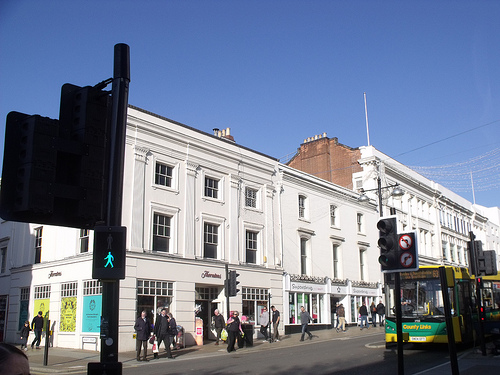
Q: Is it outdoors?
A: Yes, it is outdoors.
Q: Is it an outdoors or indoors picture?
A: It is outdoors.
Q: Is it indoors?
A: No, it is outdoors.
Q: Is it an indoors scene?
A: No, it is outdoors.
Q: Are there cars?
A: No, there are no cars.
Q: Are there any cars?
A: No, there are no cars.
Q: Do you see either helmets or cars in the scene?
A: No, there are no cars or helmets.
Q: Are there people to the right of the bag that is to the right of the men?
A: Yes, there is a person to the right of the bag.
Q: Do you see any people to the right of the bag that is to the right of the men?
A: Yes, there is a person to the right of the bag.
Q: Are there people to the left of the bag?
A: No, the person is to the right of the bag.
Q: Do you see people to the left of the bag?
A: No, the person is to the right of the bag.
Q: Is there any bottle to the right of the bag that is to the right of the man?
A: No, there is a person to the right of the bag.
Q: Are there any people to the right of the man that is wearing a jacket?
A: No, the person is to the left of the man.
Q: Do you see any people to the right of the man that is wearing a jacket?
A: No, the person is to the left of the man.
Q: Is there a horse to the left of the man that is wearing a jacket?
A: No, there is a person to the left of the man.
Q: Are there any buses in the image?
A: Yes, there is a bus.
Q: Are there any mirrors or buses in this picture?
A: Yes, there is a bus.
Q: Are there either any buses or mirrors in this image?
A: Yes, there is a bus.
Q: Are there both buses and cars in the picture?
A: No, there is a bus but no cars.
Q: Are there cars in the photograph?
A: No, there are no cars.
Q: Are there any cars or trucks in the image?
A: No, there are no cars or trucks.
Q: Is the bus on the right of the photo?
A: Yes, the bus is on the right of the image.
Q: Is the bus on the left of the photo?
A: No, the bus is on the right of the image.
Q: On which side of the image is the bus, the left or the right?
A: The bus is on the right of the image.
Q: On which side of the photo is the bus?
A: The bus is on the right of the image.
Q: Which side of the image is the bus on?
A: The bus is on the right of the image.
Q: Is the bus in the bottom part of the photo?
A: Yes, the bus is in the bottom of the image.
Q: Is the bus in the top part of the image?
A: No, the bus is in the bottom of the image.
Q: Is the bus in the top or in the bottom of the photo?
A: The bus is in the bottom of the image.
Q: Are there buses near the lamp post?
A: Yes, there is a bus near the lamp post.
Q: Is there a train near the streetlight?
A: No, there is a bus near the streetlight.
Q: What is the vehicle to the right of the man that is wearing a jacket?
A: The vehicle is a bus.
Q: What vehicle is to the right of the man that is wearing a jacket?
A: The vehicle is a bus.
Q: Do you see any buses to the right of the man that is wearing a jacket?
A: Yes, there is a bus to the right of the man.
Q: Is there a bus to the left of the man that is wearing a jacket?
A: No, the bus is to the right of the man.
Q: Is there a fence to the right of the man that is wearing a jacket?
A: No, there is a bus to the right of the man.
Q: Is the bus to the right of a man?
A: Yes, the bus is to the right of a man.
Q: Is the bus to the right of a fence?
A: No, the bus is to the right of a man.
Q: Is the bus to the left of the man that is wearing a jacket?
A: No, the bus is to the right of the man.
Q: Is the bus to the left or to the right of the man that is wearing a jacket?
A: The bus is to the right of the man.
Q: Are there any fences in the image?
A: No, there are no fences.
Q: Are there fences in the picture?
A: No, there are no fences.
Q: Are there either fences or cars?
A: No, there are no fences or cars.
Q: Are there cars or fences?
A: No, there are no fences or cars.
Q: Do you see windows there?
A: Yes, there is a window.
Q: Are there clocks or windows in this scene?
A: Yes, there is a window.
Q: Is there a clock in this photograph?
A: No, there are no clocks.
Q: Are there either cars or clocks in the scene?
A: No, there are no clocks or cars.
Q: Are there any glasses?
A: No, there are no glasses.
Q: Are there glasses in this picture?
A: No, there are no glasses.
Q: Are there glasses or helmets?
A: No, there are no glasses or helmets.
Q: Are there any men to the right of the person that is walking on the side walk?
A: Yes, there is a man to the right of the person.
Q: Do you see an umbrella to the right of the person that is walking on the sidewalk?
A: No, there is a man to the right of the person.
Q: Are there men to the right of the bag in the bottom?
A: Yes, there is a man to the right of the bag.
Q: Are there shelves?
A: No, there are no shelves.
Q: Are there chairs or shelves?
A: No, there are no shelves or chairs.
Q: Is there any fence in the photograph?
A: No, there are no fences.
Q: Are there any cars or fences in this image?
A: No, there are no fences or cars.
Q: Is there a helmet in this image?
A: No, there are no helmets.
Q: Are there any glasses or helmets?
A: No, there are no helmets or glasses.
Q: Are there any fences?
A: No, there are no fences.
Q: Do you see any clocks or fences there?
A: No, there are no fences or clocks.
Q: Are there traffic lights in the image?
A: Yes, there is a traffic light.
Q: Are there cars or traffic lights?
A: Yes, there is a traffic light.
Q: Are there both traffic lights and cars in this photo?
A: No, there is a traffic light but no cars.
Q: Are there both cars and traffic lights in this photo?
A: No, there is a traffic light but no cars.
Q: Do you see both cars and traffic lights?
A: No, there is a traffic light but no cars.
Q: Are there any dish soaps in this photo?
A: No, there are no dish soaps.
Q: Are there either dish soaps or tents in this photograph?
A: No, there are no dish soaps or tents.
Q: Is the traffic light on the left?
A: Yes, the traffic light is on the left of the image.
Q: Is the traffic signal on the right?
A: No, the traffic signal is on the left of the image.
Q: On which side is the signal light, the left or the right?
A: The signal light is on the left of the image.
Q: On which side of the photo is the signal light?
A: The signal light is on the left of the image.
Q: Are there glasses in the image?
A: No, there are no glasses.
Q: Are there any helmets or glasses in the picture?
A: No, there are no glasses or helmets.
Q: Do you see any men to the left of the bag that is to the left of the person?
A: Yes, there is a man to the left of the bag.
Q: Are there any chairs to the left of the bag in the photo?
A: No, there is a man to the left of the bag.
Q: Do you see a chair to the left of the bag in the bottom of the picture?
A: No, there is a man to the left of the bag.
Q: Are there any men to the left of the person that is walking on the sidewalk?
A: Yes, there is a man to the left of the person.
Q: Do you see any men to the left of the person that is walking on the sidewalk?
A: Yes, there is a man to the left of the person.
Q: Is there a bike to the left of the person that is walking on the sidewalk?
A: No, there is a man to the left of the person.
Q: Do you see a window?
A: Yes, there is a window.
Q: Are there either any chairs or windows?
A: Yes, there is a window.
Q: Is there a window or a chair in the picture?
A: Yes, there is a window.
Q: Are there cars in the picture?
A: No, there are no cars.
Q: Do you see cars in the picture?
A: No, there are no cars.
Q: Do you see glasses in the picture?
A: No, there are no glasses.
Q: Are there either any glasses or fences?
A: No, there are no glasses or fences.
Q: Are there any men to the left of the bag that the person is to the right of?
A: Yes, there are men to the left of the bag.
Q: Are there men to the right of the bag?
A: No, the men are to the left of the bag.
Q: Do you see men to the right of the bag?
A: No, the men are to the left of the bag.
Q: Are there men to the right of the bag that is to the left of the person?
A: No, the men are to the left of the bag.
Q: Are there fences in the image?
A: No, there are no fences.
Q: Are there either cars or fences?
A: No, there are no fences or cars.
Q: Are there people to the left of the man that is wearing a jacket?
A: Yes, there are people to the left of the man.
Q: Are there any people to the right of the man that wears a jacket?
A: No, the people are to the left of the man.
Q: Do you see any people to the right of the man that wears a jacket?
A: No, the people are to the left of the man.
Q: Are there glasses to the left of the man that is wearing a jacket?
A: No, there are people to the left of the man.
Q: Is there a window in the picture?
A: Yes, there are windows.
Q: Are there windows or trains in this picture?
A: Yes, there are windows.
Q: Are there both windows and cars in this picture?
A: No, there are windows but no cars.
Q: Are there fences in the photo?
A: No, there are no fences.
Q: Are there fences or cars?
A: No, there are no fences or cars.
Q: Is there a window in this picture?
A: Yes, there is a window.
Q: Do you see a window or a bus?
A: Yes, there is a window.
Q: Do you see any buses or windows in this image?
A: Yes, there is a window.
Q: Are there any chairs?
A: No, there are no chairs.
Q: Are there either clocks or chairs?
A: No, there are no chairs or clocks.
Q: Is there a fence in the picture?
A: No, there are no fences.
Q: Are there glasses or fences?
A: No, there are no fences or glasses.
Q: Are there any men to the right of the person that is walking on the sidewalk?
A: Yes, there is a man to the right of the person.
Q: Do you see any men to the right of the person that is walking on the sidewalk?
A: Yes, there is a man to the right of the person.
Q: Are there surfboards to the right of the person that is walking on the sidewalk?
A: No, there is a man to the right of the person.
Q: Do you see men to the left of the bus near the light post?
A: Yes, there is a man to the left of the bus.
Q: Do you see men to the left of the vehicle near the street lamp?
A: Yes, there is a man to the left of the bus.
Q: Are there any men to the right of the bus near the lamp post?
A: No, the man is to the left of the bus.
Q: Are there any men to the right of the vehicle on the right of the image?
A: No, the man is to the left of the bus.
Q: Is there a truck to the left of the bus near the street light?
A: No, there is a man to the left of the bus.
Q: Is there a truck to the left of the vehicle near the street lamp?
A: No, there is a man to the left of the bus.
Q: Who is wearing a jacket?
A: The man is wearing a jacket.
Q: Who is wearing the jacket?
A: The man is wearing a jacket.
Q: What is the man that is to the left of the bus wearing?
A: The man is wearing a jacket.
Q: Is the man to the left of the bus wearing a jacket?
A: Yes, the man is wearing a jacket.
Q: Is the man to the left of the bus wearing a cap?
A: No, the man is wearing a jacket.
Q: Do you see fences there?
A: No, there are no fences.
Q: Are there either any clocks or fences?
A: No, there are no fences or clocks.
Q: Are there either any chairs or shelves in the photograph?
A: No, there are no chairs or shelves.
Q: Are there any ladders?
A: No, there are no ladders.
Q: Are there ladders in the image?
A: No, there are no ladders.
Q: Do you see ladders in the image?
A: No, there are no ladders.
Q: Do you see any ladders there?
A: No, there are no ladders.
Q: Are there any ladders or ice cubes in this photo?
A: No, there are no ladders or ice cubes.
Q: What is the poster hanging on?
A: The poster is hanging on the wall.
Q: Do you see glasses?
A: No, there are no glasses.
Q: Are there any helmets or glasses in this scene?
A: No, there are no glasses or helmets.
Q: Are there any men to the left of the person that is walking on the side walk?
A: Yes, there is a man to the left of the person.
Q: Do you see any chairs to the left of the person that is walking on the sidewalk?
A: No, there is a man to the left of the person.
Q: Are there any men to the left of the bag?
A: Yes, there is a man to the left of the bag.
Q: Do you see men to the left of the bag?
A: Yes, there is a man to the left of the bag.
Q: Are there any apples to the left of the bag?
A: No, there is a man to the left of the bag.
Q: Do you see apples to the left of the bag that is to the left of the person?
A: No, there is a man to the left of the bag.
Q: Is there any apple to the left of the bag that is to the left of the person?
A: No, there is a man to the left of the bag.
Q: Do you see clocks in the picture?
A: No, there are no clocks.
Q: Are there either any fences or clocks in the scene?
A: No, there are no clocks or fences.